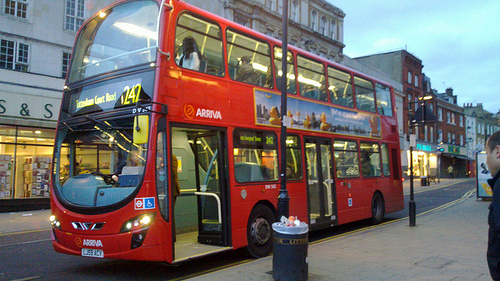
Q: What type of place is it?
A: It is a street.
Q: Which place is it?
A: It is a street.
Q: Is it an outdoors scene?
A: Yes, it is outdoors.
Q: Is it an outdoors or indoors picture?
A: It is outdoors.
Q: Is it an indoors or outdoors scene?
A: It is outdoors.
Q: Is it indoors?
A: No, it is outdoors.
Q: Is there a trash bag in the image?
A: Yes, there is a trash bag.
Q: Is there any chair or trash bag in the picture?
A: Yes, there is a trash bag.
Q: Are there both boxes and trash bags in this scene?
A: No, there is a trash bag but no boxes.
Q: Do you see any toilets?
A: No, there are no toilets.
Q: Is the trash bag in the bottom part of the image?
A: Yes, the trash bag is in the bottom of the image.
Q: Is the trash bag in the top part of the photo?
A: No, the trash bag is in the bottom of the image.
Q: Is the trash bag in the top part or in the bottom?
A: The trash bag is in the bottom of the image.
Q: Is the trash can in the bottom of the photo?
A: Yes, the trash can is in the bottom of the image.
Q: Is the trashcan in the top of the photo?
A: No, the trashcan is in the bottom of the image.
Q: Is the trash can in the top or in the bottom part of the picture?
A: The trash can is in the bottom of the image.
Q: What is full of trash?
A: The garbage can is full of trash.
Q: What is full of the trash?
A: The garbage can is full of trash.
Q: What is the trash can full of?
A: The trash can is full of trash.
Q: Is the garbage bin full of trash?
A: Yes, the garbage bin is full of trash.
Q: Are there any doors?
A: Yes, there is a door.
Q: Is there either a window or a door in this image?
A: Yes, there is a door.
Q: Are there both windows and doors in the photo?
A: Yes, there are both a door and windows.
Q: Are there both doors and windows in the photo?
A: Yes, there are both a door and windows.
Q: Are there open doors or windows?
A: Yes, there is an open door.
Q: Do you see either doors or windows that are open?
A: Yes, the door is open.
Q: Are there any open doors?
A: Yes, there is an open door.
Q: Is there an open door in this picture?
A: Yes, there is an open door.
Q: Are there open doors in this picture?
A: Yes, there is an open door.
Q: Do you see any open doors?
A: Yes, there is an open door.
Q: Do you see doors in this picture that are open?
A: Yes, there is a door that is open.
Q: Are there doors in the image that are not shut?
A: Yes, there is a open door.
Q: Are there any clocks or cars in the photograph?
A: No, there are no cars or clocks.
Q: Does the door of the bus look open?
A: Yes, the door is open.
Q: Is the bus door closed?
A: No, the door is open.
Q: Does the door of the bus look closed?
A: No, the door is open.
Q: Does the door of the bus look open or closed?
A: The door is open.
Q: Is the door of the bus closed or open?
A: The door is open.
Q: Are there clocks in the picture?
A: No, there are no clocks.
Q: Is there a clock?
A: No, there are no clocks.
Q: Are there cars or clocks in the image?
A: No, there are no clocks or cars.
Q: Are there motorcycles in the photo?
A: No, there are no motorcycles.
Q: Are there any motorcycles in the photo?
A: No, there are no motorcycles.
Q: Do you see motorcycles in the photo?
A: No, there are no motorcycles.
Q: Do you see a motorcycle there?
A: No, there are no motorcycles.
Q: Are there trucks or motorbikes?
A: No, there are no motorbikes or trucks.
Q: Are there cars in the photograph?
A: No, there are no cars.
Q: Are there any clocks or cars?
A: No, there are no cars or clocks.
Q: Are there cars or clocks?
A: No, there are no cars or clocks.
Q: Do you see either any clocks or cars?
A: No, there are no cars or clocks.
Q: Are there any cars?
A: No, there are no cars.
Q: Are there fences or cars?
A: No, there are no cars or fences.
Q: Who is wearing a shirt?
A: The people are wearing a shirt.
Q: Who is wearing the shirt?
A: The people are wearing a shirt.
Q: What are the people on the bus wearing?
A: The people are wearing a shirt.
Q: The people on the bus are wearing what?
A: The people are wearing a shirt.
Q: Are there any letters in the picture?
A: Yes, there are letters.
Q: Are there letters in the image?
A: Yes, there are letters.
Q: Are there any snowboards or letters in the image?
A: Yes, there are letters.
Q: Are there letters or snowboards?
A: Yes, there are letters.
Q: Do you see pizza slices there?
A: No, there are no pizza slices.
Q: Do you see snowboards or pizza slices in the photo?
A: No, there are no pizza slices or snowboards.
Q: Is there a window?
A: Yes, there is a window.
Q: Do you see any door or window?
A: Yes, there is a window.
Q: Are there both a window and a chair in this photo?
A: No, there is a window but no chairs.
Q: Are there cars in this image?
A: No, there are no cars.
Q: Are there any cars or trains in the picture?
A: No, there are no cars or trains.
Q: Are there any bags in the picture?
A: Yes, there is a bag.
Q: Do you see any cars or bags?
A: Yes, there is a bag.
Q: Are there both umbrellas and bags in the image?
A: No, there is a bag but no umbrellas.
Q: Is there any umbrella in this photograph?
A: No, there are no umbrellas.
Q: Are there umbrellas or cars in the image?
A: No, there are no umbrellas or cars.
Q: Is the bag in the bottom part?
A: Yes, the bag is in the bottom of the image.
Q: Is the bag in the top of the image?
A: No, the bag is in the bottom of the image.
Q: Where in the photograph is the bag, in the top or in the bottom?
A: The bag is in the bottom of the image.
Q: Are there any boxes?
A: No, there are no boxes.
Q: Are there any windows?
A: Yes, there are windows.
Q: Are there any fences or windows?
A: Yes, there are windows.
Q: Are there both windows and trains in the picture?
A: No, there are windows but no trains.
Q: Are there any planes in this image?
A: No, there are no planes.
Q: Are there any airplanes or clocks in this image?
A: No, there are no airplanes or clocks.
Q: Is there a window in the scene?
A: Yes, there is a window.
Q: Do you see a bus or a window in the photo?
A: Yes, there is a window.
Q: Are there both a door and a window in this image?
A: Yes, there are both a window and a door.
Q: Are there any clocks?
A: No, there are no clocks.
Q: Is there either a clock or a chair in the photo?
A: No, there are no clocks or chairs.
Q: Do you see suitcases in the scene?
A: No, there are no suitcases.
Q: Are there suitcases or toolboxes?
A: No, there are no suitcases or toolboxes.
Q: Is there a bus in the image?
A: Yes, there is a bus.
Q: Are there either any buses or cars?
A: Yes, there is a bus.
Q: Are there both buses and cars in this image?
A: No, there is a bus but no cars.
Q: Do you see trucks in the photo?
A: No, there are no trucks.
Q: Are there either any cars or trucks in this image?
A: No, there are no trucks or cars.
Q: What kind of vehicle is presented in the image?
A: The vehicle is a bus.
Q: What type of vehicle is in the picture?
A: The vehicle is a bus.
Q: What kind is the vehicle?
A: The vehicle is a bus.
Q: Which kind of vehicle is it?
A: The vehicle is a bus.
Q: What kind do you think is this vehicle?
A: This is a bus.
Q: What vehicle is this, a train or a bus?
A: This is a bus.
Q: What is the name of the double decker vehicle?
A: The vehicle is a bus.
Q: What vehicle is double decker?
A: The vehicle is a bus.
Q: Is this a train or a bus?
A: This is a bus.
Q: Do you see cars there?
A: No, there are no cars.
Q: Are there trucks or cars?
A: No, there are no cars or trucks.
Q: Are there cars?
A: No, there are no cars.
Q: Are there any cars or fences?
A: No, there are no cars or fences.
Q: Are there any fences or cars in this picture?
A: No, there are no cars or fences.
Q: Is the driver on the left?
A: Yes, the driver is on the left of the image.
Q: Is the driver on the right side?
A: No, the driver is on the left of the image.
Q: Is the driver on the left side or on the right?
A: The driver is on the left of the image.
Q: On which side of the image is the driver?
A: The driver is on the left of the image.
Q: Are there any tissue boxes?
A: No, there are no tissue boxes.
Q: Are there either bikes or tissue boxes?
A: No, there are no tissue boxes or bikes.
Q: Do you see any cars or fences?
A: No, there are no cars or fences.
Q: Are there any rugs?
A: No, there are no rugs.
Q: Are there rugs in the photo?
A: No, there are no rugs.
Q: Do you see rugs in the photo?
A: No, there are no rugs.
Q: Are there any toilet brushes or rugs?
A: No, there are no rugs or toilet brushes.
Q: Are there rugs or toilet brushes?
A: No, there are no rugs or toilet brushes.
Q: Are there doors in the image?
A: Yes, there are doors.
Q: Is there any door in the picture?
A: Yes, there are doors.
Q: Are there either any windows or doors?
A: Yes, there are doors.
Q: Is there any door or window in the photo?
A: Yes, there are doors.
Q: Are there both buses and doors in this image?
A: Yes, there are both doors and a bus.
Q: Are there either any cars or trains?
A: No, there are no cars or trains.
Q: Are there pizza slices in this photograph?
A: No, there are no pizza slices.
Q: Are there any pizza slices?
A: No, there are no pizza slices.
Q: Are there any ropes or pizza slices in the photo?
A: No, there are no pizza slices or ropes.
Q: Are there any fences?
A: No, there are no fences.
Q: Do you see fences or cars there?
A: No, there are no fences or cars.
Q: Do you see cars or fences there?
A: No, there are no fences or cars.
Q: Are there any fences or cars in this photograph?
A: No, there are no fences or cars.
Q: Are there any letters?
A: Yes, there are letters.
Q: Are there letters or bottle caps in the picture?
A: Yes, there are letters.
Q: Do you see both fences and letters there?
A: No, there are letters but no fences.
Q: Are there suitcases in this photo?
A: No, there are no suitcases.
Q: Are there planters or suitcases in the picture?
A: No, there are no suitcases or planters.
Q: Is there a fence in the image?
A: No, there are no fences.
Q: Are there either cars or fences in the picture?
A: No, there are no fences or cars.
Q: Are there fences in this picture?
A: No, there are no fences.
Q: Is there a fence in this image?
A: No, there are no fences.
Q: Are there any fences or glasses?
A: No, there are no fences or glasses.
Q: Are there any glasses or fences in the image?
A: No, there are no fences or glasses.